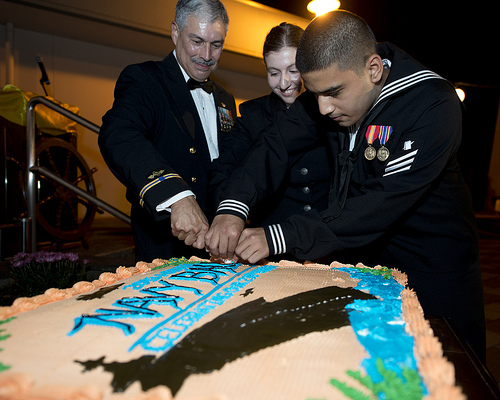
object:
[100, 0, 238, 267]
man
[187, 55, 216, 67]
mustache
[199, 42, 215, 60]
nose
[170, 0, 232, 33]
hair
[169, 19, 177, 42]
ear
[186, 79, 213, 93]
tie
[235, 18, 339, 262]
woman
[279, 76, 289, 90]
nose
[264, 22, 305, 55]
hair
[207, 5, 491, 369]
man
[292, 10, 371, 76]
hair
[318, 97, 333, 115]
nose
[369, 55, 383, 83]
ear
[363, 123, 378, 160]
medal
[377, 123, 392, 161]
medal